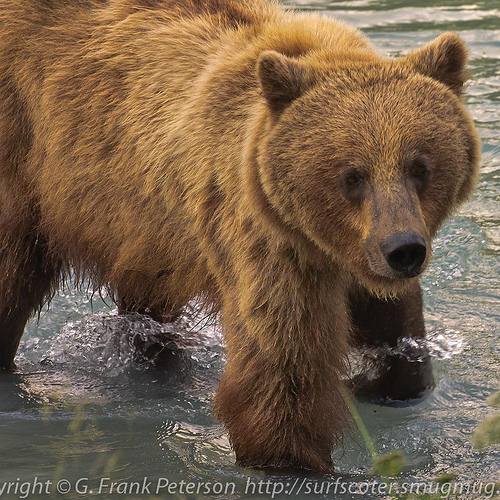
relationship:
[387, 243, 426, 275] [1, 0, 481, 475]
nose of bear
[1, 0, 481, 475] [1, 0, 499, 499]
bear in water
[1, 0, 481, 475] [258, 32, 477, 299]
bear has head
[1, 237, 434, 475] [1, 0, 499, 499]
legs in water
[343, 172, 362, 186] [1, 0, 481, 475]
eye of bear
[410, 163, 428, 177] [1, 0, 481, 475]
eye of bear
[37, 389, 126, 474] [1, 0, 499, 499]
grass under water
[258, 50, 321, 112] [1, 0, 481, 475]
ear of bear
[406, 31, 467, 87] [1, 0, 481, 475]
ear of bear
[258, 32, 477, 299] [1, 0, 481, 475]
head of bear